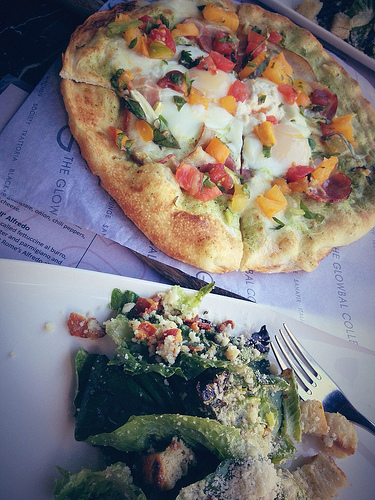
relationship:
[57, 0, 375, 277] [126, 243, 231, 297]
food sitting on plate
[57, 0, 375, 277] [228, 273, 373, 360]
food covered with paper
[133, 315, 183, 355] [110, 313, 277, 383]
cheese on leaf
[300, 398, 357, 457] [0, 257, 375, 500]
crouton on plate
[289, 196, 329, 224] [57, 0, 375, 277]
scallions on food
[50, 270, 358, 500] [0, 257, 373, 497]
food on plate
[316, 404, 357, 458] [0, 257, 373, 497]
crouton on plate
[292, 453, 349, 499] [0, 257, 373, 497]
crouton on plate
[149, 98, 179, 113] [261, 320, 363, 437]
wall of a fork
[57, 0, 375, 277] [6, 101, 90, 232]
food on a paper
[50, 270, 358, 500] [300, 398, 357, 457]
food and crouton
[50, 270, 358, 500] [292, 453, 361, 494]
food and crouton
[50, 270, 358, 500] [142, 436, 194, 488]
food and crouton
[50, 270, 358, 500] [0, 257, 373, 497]
food on a plate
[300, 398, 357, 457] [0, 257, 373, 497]
crouton on a plate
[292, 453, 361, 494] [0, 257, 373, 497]
crouton on a plate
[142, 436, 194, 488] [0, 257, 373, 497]
crouton on a plate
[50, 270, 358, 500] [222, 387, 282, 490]
food with cheese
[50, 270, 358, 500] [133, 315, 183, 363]
food with cheese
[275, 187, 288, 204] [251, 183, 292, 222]
bit of pepper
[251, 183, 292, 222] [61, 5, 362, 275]
pepper on a pizza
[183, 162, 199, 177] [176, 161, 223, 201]
part of a tomato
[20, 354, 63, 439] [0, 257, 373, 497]
part of a plate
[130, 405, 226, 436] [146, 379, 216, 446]
edge of a leaf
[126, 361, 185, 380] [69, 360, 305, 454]
edge of a leaf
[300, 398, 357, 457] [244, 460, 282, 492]
crouton with cheese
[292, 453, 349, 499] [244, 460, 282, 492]
crouton with cheese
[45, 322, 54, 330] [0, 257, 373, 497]
crumb on plate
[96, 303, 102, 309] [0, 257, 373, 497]
crumb on plate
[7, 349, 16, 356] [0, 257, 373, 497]
crumb on plate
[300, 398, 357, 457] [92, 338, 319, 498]
crouton mixed with salad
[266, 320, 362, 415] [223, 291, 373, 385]
motorcycle on edge plate